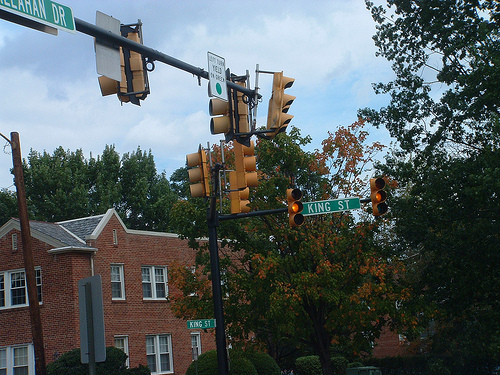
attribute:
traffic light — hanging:
[252, 66, 297, 139]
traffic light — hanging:
[208, 81, 253, 144]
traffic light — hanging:
[98, 20, 149, 108]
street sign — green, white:
[0, 1, 76, 29]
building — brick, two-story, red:
[0, 208, 424, 374]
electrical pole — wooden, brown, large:
[10, 132, 47, 374]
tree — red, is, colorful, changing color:
[164, 117, 422, 374]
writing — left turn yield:
[208, 53, 226, 83]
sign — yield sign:
[206, 52, 230, 103]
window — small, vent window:
[111, 228, 118, 246]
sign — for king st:
[302, 195, 362, 215]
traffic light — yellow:
[285, 186, 306, 231]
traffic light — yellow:
[369, 177, 389, 217]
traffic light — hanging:
[228, 168, 252, 213]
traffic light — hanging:
[233, 139, 261, 189]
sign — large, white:
[75, 273, 107, 374]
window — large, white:
[6, 270, 29, 305]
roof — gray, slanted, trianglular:
[1, 214, 104, 246]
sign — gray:
[95, 12, 124, 84]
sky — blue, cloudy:
[0, 1, 500, 253]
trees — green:
[0, 144, 216, 232]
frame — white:
[6, 344, 34, 374]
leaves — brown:
[302, 117, 412, 313]